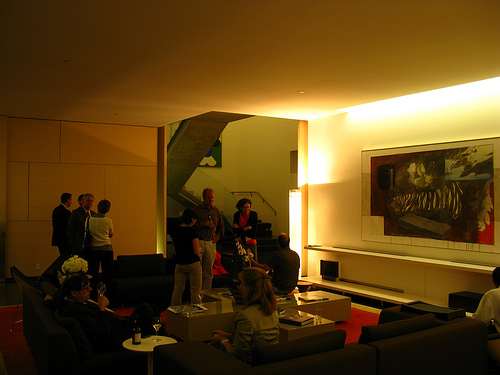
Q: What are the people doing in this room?
A: Drinking and talking.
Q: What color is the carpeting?
A: Red.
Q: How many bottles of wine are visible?
A: One.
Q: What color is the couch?
A: Brown.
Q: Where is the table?
A: In the middle of the room.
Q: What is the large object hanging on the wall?
A: A painting.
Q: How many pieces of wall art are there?
A: One.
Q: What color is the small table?
A: White.